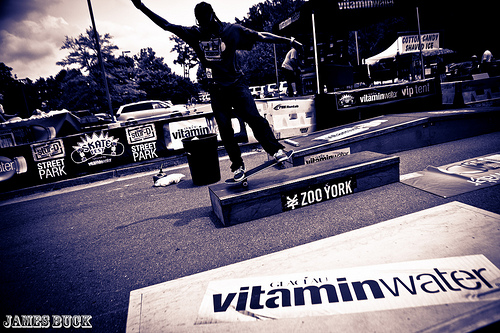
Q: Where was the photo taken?
A: It was taken at the road.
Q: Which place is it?
A: It is a road.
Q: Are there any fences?
A: No, there are no fences.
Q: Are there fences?
A: No, there are no fences.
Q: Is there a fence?
A: No, there are no fences.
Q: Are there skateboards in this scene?
A: Yes, there is a skateboard.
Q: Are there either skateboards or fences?
A: Yes, there is a skateboard.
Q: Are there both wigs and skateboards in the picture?
A: No, there is a skateboard but no wigs.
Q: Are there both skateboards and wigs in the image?
A: No, there is a skateboard but no wigs.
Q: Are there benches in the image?
A: No, there are no benches.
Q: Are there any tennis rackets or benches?
A: No, there are no benches or tennis rackets.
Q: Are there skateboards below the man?
A: Yes, there is a skateboard below the man.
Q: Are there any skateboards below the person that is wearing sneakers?
A: Yes, there is a skateboard below the man.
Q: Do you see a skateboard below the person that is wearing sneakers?
A: Yes, there is a skateboard below the man.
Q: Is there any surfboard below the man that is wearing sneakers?
A: No, there is a skateboard below the man.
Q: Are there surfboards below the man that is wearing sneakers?
A: No, there is a skateboard below the man.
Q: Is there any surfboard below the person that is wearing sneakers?
A: No, there is a skateboard below the man.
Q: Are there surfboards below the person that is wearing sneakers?
A: No, there is a skateboard below the man.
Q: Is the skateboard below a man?
A: Yes, the skateboard is below a man.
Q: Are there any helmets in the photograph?
A: No, there are no helmets.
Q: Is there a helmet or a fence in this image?
A: No, there are no helmets or fences.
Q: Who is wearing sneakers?
A: The man is wearing sneakers.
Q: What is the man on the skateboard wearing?
A: The man is wearing sneakers.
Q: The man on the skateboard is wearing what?
A: The man is wearing sneakers.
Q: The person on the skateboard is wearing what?
A: The man is wearing sneakers.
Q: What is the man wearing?
A: The man is wearing sneakers.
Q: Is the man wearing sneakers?
A: Yes, the man is wearing sneakers.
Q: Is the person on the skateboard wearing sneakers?
A: Yes, the man is wearing sneakers.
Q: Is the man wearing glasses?
A: No, the man is wearing sneakers.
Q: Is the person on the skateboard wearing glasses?
A: No, the man is wearing sneakers.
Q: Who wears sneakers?
A: The man wears sneakers.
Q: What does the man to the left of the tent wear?
A: The man wears sneakers.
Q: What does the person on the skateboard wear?
A: The man wears sneakers.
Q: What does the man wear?
A: The man wears sneakers.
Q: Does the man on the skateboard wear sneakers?
A: Yes, the man wears sneakers.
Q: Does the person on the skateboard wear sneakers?
A: Yes, the man wears sneakers.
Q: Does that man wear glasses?
A: No, the man wears sneakers.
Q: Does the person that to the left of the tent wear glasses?
A: No, the man wears sneakers.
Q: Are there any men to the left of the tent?
A: Yes, there is a man to the left of the tent.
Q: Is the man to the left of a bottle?
A: No, the man is to the left of the tent.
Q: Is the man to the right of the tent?
A: No, the man is to the left of the tent.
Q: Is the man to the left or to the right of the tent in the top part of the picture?
A: The man is to the left of the tent.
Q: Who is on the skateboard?
A: The man is on the skateboard.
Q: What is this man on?
A: The man is on the skateboard.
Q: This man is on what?
A: The man is on the skateboard.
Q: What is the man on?
A: The man is on the skateboard.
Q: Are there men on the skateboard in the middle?
A: Yes, there is a man on the skateboard.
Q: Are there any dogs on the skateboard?
A: No, there is a man on the skateboard.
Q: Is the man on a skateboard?
A: Yes, the man is on a skateboard.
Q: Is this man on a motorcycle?
A: No, the man is on a skateboard.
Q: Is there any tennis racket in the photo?
A: No, there are no rackets.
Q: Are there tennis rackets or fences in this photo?
A: No, there are no tennis rackets or fences.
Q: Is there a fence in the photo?
A: No, there are no fences.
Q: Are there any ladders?
A: No, there are no ladders.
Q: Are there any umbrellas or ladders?
A: No, there are no ladders or umbrellas.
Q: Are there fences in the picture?
A: No, there are no fences.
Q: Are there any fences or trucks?
A: No, there are no fences or trucks.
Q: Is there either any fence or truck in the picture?
A: No, there are no fences or trucks.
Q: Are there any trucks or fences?
A: No, there are no fences or trucks.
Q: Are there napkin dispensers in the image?
A: No, there are no napkin dispensers.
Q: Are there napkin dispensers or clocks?
A: No, there are no napkin dispensers or clocks.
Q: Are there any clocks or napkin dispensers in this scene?
A: No, there are no napkin dispensers or clocks.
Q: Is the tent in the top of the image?
A: Yes, the tent is in the top of the image.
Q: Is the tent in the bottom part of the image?
A: No, the tent is in the top of the image.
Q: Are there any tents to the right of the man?
A: Yes, there is a tent to the right of the man.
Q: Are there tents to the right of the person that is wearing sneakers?
A: Yes, there is a tent to the right of the man.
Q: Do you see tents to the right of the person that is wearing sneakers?
A: Yes, there is a tent to the right of the man.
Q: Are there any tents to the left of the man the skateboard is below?
A: No, the tent is to the right of the man.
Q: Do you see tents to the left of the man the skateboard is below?
A: No, the tent is to the right of the man.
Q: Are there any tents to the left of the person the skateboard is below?
A: No, the tent is to the right of the man.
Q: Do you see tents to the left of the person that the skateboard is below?
A: No, the tent is to the right of the man.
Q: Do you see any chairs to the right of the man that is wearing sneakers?
A: No, there is a tent to the right of the man.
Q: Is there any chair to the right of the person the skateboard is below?
A: No, there is a tent to the right of the man.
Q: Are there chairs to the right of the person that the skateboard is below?
A: No, there is a tent to the right of the man.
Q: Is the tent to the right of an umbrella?
A: No, the tent is to the right of the man.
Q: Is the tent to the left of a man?
A: No, the tent is to the right of a man.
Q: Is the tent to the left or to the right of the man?
A: The tent is to the right of the man.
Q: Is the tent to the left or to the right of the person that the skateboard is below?
A: The tent is to the right of the man.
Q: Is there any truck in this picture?
A: No, there are no trucks.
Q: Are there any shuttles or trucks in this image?
A: No, there are no trucks or shuttles.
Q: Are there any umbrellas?
A: No, there are no umbrellas.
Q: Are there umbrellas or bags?
A: No, there are no umbrellas or bags.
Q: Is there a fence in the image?
A: No, there are no fences.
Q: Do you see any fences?
A: No, there are no fences.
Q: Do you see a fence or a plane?
A: No, there are no fences or airplanes.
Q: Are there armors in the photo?
A: No, there are no armors.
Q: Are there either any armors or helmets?
A: No, there are no armors or helmets.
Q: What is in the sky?
A: The clouds are in the sky.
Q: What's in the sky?
A: The clouds are in the sky.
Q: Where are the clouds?
A: The clouds are in the sky.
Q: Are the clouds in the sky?
A: Yes, the clouds are in the sky.